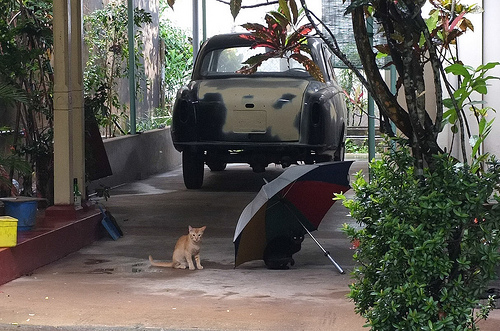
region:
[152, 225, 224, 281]
cat sitting on ground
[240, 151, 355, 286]
umbrella on the ground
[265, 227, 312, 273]
cat under the umbrella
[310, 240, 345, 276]
handle on the umbrella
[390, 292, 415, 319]
leaves on green plant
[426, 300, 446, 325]
leaves on green plant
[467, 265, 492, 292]
leaves on green plant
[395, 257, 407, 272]
leaves on green plant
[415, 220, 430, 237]
leaves on green plant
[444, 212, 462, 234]
leaves on green plant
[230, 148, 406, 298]
umbrella laying on ground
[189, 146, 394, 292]
the umbrella is open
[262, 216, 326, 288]
cat sitting under umbrella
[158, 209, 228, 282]
the cat is orange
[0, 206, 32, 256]
yellow container on ground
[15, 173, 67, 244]
blue object on ground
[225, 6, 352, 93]
pink spots on plant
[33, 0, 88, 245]
the posts are white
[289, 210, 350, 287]
umbrella handle is silver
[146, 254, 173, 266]
orange cat's tail against concrete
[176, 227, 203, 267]
thin striped orange cat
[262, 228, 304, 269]
black cat in the shadows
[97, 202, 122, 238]
a broken shovel head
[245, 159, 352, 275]
a black cat sitting under a black umbrella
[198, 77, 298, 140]
the trunk of an old car without a license plate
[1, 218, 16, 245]
yellow bucket in a garage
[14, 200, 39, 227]
side of a blue bucket in a garage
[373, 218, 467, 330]
green shrubs outside of a house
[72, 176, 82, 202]
a bottle of green fluid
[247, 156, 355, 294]
A black fire under an umbrella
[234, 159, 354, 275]
The umbrella is on the ground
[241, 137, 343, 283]
The umbrella is red and black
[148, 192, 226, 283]
A small yellow kitten on the ground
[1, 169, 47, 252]
Two buckets on the ledge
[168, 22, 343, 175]
a very old car that needs a paint job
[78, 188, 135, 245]
A blue scoop on the ground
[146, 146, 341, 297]
Two kittens in a driveway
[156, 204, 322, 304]
A black kitten and a yellow kitten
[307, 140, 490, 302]
A bush near the carport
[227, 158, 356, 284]
black cat sitting under an umbrella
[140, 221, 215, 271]
orange cat sitting on driveway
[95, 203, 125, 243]
blue dustpan leaning against a a low wall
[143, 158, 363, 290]
oranage cat sitting next to an open umbrella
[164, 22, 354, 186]
beat-up car parked in driveway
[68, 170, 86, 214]
bottle next to a column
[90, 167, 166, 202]
moisture in corner of driveway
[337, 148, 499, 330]
green bush at end of driveway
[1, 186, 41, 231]
blue planter sitting next to a yellow container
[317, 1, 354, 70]
building in the distance